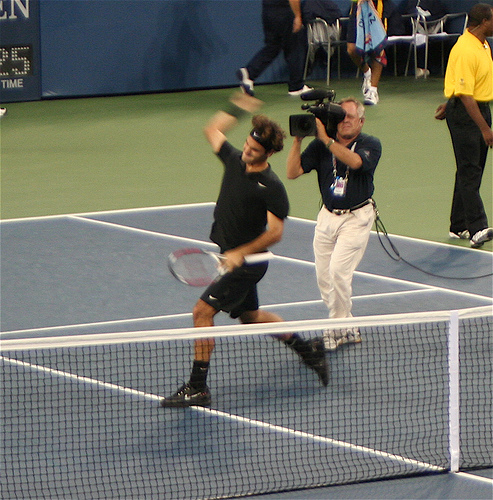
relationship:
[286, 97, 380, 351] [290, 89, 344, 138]
man has video camera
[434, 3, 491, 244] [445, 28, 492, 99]
man has shirt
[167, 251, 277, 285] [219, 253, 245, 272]
racket inside of hand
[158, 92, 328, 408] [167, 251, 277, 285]
man holding racket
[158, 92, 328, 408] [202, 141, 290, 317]
man wearing clothing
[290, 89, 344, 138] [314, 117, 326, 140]
video camera inside of hand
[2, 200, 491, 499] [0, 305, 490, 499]
tennis court has net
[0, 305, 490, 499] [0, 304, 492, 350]
net has top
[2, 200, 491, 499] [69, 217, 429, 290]
tennis court has line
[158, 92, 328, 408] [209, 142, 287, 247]
man has shirt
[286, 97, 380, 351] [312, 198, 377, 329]
man hs pants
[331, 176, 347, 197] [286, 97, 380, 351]
vip media pass in front of man